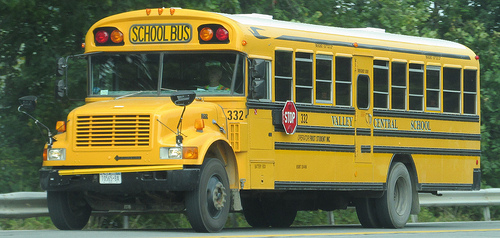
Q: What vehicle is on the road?
A: School bus.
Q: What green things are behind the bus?
A: Trees.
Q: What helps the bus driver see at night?
A: The headlights.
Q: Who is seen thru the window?
A: The bus driver.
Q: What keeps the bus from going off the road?
A: The guardrail.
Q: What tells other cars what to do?
A: Stop sign on bus.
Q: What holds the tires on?
A: The lugnuts.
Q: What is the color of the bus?
A: Yellow.